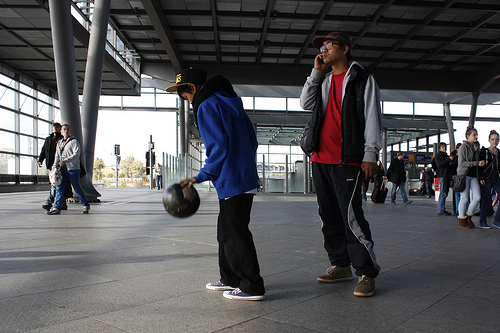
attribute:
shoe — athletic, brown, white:
[316, 265, 353, 282]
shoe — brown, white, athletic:
[352, 271, 374, 297]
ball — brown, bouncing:
[162, 181, 199, 217]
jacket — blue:
[118, 57, 306, 319]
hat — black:
[167, 60, 213, 118]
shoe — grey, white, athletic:
[200, 280, 234, 292]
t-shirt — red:
[308, 73, 345, 163]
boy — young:
[153, 67, 279, 308]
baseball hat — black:
[162, 65, 204, 89]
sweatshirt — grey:
[300, 62, 382, 163]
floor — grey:
[2, 191, 493, 332]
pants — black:
[185, 127, 287, 327]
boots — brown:
[458, 211, 477, 229]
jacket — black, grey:
[189, 92, 260, 198]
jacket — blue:
[198, 98, 258, 196]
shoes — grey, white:
[193, 278, 275, 307]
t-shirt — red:
[308, 65, 358, 165]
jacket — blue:
[187, 95, 262, 192]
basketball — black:
[157, 181, 201, 218]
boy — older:
[297, 31, 385, 296]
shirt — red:
[302, 66, 354, 163]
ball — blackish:
[164, 181, 200, 216]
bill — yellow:
[162, 83, 179, 96]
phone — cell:
[308, 44, 336, 73]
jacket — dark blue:
[147, 83, 287, 217]